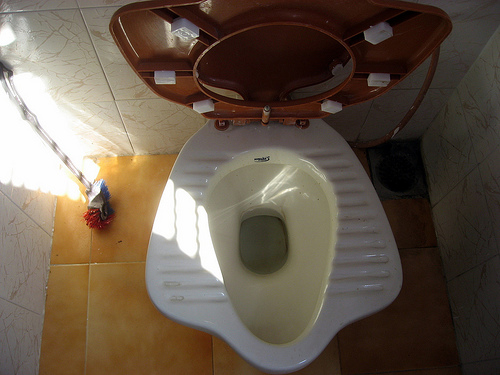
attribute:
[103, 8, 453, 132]
seat — Odd shaped toilet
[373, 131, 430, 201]
cleaner — Toilet bowl 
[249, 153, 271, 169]
logo — Black 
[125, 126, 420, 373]
seat — toilet 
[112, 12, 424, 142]
seat — Odd shaped brown toilet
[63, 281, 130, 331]
floor — Light orange tiled 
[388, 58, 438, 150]
tube — Brown plumbing 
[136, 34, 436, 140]
cushions — White 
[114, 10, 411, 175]
seat — bottom 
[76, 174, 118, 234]
brush — red, blue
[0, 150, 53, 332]
tile — white, gold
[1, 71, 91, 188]
handle — white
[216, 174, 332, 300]
water — dirty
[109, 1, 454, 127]
lid — up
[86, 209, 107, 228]
bristles — red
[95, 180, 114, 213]
bristles — blue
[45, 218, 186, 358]
floor — brown, tiled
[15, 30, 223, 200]
walls — white, cracked, tan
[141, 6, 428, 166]
lid — brown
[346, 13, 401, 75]
stoppers — white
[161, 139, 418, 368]
seat — white, dirty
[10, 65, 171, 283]
cleaner — silver, leaning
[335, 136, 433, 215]
plate — square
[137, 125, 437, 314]
toilet — white, porcelain, black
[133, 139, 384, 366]
toilet — odd, white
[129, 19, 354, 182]
seat — lifted up, brown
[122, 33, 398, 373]
toilet — porcelain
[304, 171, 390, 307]
seat — ridged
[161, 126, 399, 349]
toilet — porcelain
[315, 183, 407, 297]
seat — ridged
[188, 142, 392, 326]
seat — ridged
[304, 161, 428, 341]
seat — ridged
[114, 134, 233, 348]
seat — ridged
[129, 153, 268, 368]
seat — ridged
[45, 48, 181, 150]
walls — tiled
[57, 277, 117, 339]
tile — brown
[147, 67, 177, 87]
square — white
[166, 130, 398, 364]
toliet — White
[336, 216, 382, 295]
seat — ridged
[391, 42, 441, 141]
cord — brown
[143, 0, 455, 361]
toilet — porcelain